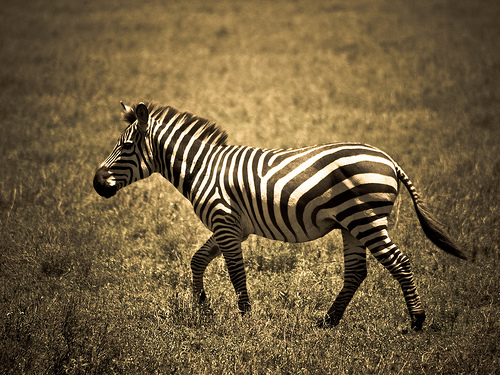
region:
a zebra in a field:
[64, 90, 458, 324]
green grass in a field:
[91, 290, 158, 372]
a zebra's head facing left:
[85, 92, 188, 211]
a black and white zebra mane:
[146, 100, 228, 144]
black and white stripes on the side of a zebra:
[233, 157, 358, 209]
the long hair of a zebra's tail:
[409, 200, 482, 263]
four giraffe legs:
[181, 225, 442, 337]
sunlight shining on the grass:
[177, 10, 429, 128]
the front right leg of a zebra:
[181, 225, 214, 307]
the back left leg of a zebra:
[370, 232, 440, 345]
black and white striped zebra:
[71, 94, 470, 332]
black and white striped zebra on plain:
[81, 99, 463, 329]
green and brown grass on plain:
[16, 16, 168, 91]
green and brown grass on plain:
[147, 9, 291, 103]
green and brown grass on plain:
[259, 16, 422, 133]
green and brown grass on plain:
[394, 29, 491, 148]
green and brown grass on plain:
[23, 114, 93, 309]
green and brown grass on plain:
[50, 210, 172, 350]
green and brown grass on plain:
[100, 319, 302, 356]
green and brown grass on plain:
[262, 253, 314, 333]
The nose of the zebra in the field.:
[86, 159, 128, 196]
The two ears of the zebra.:
[115, 93, 155, 125]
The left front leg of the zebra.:
[180, 220, 221, 299]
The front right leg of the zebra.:
[210, 214, 260, 311]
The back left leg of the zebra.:
[332, 227, 372, 324]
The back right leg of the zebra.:
[359, 223, 435, 335]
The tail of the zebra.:
[395, 160, 468, 264]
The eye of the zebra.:
[116, 138, 141, 155]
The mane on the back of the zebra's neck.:
[145, 96, 239, 146]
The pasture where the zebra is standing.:
[10, 113, 454, 370]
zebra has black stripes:
[147, 120, 467, 347]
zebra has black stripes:
[82, 60, 405, 305]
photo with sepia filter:
[2, 0, 499, 373]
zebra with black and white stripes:
[94, 98, 470, 332]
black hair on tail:
[411, 170, 477, 269]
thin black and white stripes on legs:
[179, 234, 434, 330]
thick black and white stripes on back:
[210, 137, 397, 240]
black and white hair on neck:
[128, 102, 230, 144]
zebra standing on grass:
[0, 1, 497, 373]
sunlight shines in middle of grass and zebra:
[163, 0, 383, 374]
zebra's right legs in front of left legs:
[178, 232, 435, 332]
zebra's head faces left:
[86, 102, 466, 332]